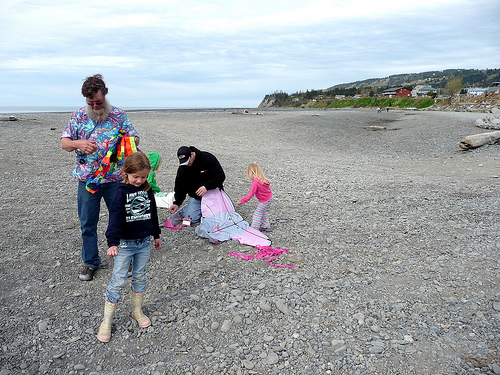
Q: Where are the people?
A: Beach.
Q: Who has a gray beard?
A: Man in the colorful shirt.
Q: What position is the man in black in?
A: Kneeling.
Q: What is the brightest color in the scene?
A: Pink.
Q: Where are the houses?
A: Beyond the stones.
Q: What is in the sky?
A: White clouds.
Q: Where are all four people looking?
A: Down at the ground.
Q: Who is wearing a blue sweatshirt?
A: Girl standing in front.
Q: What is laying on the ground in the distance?
A: Log.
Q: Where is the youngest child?
A: Behind the kneeling man.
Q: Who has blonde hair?
A: Little girl in pink.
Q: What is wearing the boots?
A: The girl.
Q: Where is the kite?
A: On the ground.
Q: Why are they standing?
A: Waiting.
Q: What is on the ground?
A: Gravel.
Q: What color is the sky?
A: Blue.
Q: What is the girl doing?
A: Standing.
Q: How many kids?
A: 2.